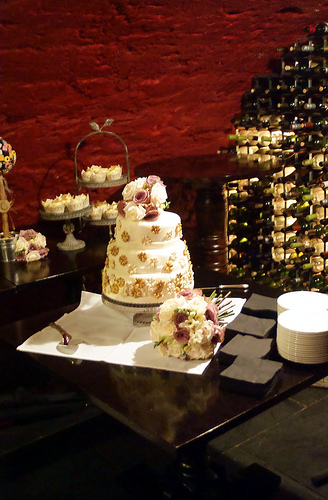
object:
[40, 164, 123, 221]
cupcakes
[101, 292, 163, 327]
stand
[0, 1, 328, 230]
ground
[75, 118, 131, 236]
metal rack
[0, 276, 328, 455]
table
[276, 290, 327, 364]
plates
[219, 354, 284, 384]
napkin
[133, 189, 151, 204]
flower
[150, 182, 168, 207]
flower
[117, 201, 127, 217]
flower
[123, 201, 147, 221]
flower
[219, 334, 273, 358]
napkin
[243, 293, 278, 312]
napkin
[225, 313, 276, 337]
napkin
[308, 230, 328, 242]
bottle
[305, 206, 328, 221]
bottle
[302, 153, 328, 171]
bottle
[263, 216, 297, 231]
bottle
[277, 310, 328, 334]
plate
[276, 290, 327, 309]
plate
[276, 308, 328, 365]
dishes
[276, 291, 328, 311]
dishes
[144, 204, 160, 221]
flower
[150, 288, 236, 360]
bouquet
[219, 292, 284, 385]
napkins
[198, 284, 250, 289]
knife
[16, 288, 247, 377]
napkins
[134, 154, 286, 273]
table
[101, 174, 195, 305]
cake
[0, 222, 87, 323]
table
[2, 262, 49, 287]
reflection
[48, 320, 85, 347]
server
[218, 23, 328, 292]
bottles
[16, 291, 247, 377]
cloth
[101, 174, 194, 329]
wedding cake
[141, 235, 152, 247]
gold flower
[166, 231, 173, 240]
gold flower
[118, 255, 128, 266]
gold flower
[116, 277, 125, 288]
gold flower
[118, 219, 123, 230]
gold flower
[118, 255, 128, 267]
frosting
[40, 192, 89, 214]
cupcakes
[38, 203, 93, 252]
stand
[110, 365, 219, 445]
reflection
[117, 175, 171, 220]
bouquet